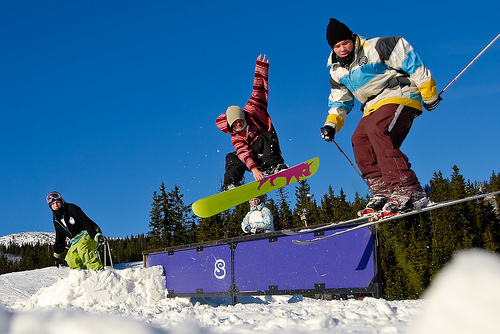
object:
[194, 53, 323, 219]
snowboarder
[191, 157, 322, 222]
snowboard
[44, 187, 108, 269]
skier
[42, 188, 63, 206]
goggles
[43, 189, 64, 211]
head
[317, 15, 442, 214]
skier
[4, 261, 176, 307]
ramp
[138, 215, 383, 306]
fence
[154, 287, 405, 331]
prints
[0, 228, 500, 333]
snow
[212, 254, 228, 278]
logo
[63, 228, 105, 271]
pants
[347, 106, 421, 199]
pants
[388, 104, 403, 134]
stripe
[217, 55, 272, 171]
shirt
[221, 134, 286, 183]
pants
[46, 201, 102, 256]
coat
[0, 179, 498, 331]
mountain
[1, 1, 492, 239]
sky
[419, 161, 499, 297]
trees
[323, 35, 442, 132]
jacket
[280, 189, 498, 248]
skis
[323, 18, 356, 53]
cap